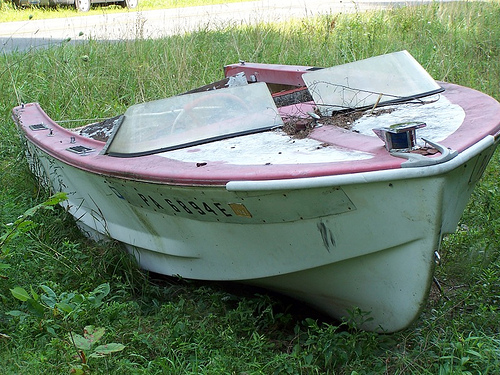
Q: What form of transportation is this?
A: Boat.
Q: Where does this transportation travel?
A: Water.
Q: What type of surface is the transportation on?
A: Grass.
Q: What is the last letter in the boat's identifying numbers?
A: E.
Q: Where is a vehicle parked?
A: Across the street.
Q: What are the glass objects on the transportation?
A: Windshields.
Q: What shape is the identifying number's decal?
A: Rectangle.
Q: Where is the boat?
A: Ground.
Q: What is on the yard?
A: Ship.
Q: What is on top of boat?
A: Windshield.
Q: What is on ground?
A: Weeds.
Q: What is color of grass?
A: Green.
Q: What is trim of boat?
A: Pink.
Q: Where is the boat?
A: On the grass.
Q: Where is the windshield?
A: On top of the boat.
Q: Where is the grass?
A: On the ground.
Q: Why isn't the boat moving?
A: It's not in the water.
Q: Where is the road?
A: In the background behind the boat.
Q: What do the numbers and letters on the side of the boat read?
A: PA 6894E.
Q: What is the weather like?
A: Sunny.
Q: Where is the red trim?
A: On the edge of the boat.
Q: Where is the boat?
A: On grass.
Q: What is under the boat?
A: Grass.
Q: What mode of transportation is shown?
A: Boat.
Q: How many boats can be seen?
A: One.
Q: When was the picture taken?
A: Daytime.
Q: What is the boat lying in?
A: Grass.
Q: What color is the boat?
A: White.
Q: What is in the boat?
A: Weeds.